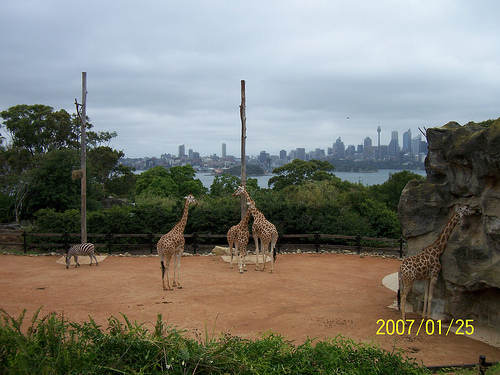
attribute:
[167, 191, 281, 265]
giraffes — standing, together, many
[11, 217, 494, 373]
enclosure — zoo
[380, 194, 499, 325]
giraffe — standing, alone, taller, tall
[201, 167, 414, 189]
water — body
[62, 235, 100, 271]
zebra — visable, grazing, black, white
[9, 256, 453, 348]
ground — dry, clay, red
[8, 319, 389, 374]
vegetation — green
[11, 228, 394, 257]
fence — wood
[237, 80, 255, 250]
pole — wooden, tall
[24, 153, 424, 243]
trees — green, tall, many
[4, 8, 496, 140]
sky — gray, cloudy, daytime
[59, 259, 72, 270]
head — bent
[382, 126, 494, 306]
structure — rock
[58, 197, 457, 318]
animals — visable, together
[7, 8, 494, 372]
habitat — not natural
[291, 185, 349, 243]
shrub — green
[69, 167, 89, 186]
hay — bale, hanging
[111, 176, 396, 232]
bushes — green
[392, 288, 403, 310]
tail — black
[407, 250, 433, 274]
spots — brown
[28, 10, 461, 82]
clouds — white, dark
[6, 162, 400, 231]
plants — green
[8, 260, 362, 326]
sand — brown